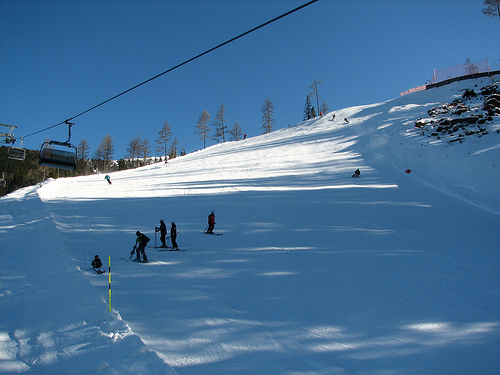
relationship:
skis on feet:
[157, 245, 189, 255] [168, 245, 179, 249]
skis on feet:
[157, 245, 189, 255] [157, 242, 166, 247]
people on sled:
[206, 210, 216, 234] [86, 265, 108, 281]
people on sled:
[170, 221, 178, 250] [86, 265, 108, 281]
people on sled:
[155, 219, 167, 247] [86, 265, 108, 281]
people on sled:
[135, 230, 150, 263] [86, 265, 108, 281]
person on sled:
[342, 157, 374, 191] [86, 265, 108, 281]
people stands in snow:
[135, 230, 150, 263] [113, 186, 291, 309]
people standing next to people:
[170, 221, 178, 250] [155, 219, 167, 247]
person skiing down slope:
[350, 167, 361, 178] [0, 78, 498, 368]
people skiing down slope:
[155, 219, 167, 247] [0, 78, 498, 368]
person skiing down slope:
[332, 113, 335, 119] [160, 128, 387, 340]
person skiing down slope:
[242, 130, 249, 139] [147, 70, 497, 187]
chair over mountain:
[39, 122, 78, 171] [2, 65, 498, 367]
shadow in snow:
[287, 125, 353, 156] [2, 67, 498, 368]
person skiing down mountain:
[103, 173, 114, 186] [2, 65, 498, 367]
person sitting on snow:
[87, 253, 106, 276] [7, 172, 499, 373]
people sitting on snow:
[135, 230, 150, 263] [7, 172, 499, 373]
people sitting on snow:
[155, 219, 167, 247] [7, 172, 499, 373]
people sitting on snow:
[170, 221, 178, 250] [7, 172, 499, 373]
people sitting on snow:
[206, 210, 216, 234] [7, 172, 499, 373]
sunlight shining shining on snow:
[394, 310, 456, 335] [223, 138, 326, 218]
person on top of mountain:
[244, 134, 247, 139] [2, 65, 498, 367]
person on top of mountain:
[317, 110, 325, 118] [2, 65, 498, 367]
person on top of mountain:
[331, 113, 336, 120] [2, 65, 498, 367]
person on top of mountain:
[342, 117, 351, 124] [2, 65, 498, 367]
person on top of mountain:
[179, 149, 184, 153] [2, 65, 498, 367]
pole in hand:
[148, 222, 163, 247] [153, 223, 163, 233]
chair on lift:
[40, 118, 79, 160] [7, 2, 340, 165]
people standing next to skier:
[135, 230, 150, 263] [149, 216, 189, 256]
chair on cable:
[39, 122, 78, 171] [34, 1, 308, 126]